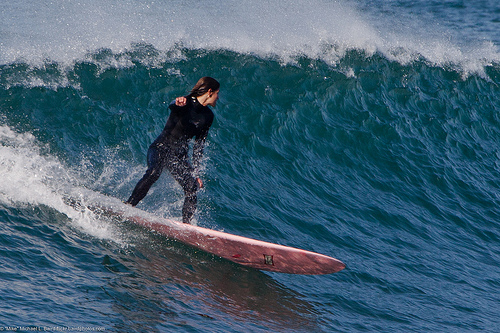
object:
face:
[212, 89, 219, 107]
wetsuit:
[123, 93, 214, 225]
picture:
[3, 1, 498, 331]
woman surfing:
[87, 48, 344, 296]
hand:
[175, 96, 186, 107]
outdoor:
[0, 0, 497, 333]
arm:
[168, 96, 187, 112]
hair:
[166, 77, 220, 120]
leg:
[122, 150, 164, 207]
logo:
[263, 254, 276, 267]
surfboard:
[63, 186, 348, 276]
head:
[196, 76, 220, 107]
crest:
[0, 0, 497, 68]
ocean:
[1, 1, 498, 333]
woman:
[124, 74, 221, 224]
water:
[1, 0, 498, 331]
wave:
[0, 0, 500, 100]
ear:
[208, 88, 213, 97]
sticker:
[262, 253, 275, 265]